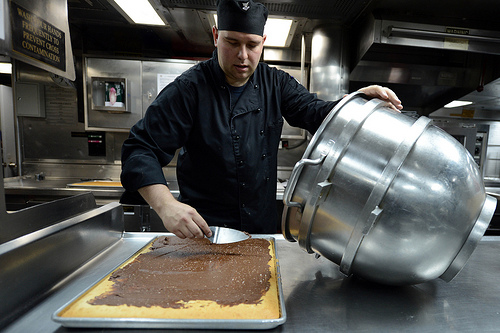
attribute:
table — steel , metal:
[38, 139, 468, 317]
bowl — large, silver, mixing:
[274, 96, 483, 305]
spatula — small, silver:
[180, 226, 276, 264]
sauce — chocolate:
[127, 246, 273, 297]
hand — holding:
[141, 191, 216, 245]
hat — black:
[211, 6, 295, 48]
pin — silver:
[233, 0, 265, 21]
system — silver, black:
[344, 22, 499, 75]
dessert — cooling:
[39, 150, 148, 192]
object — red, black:
[62, 128, 126, 161]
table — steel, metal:
[314, 270, 481, 323]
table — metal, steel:
[295, 265, 418, 329]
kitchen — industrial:
[12, 19, 500, 299]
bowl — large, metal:
[287, 107, 497, 289]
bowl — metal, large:
[283, 101, 500, 310]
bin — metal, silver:
[285, 85, 484, 330]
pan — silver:
[33, 208, 303, 322]